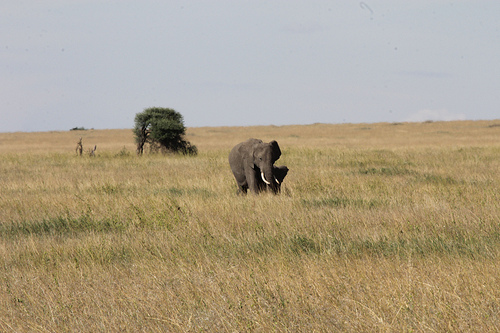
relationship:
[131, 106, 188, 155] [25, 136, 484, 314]
tree in plains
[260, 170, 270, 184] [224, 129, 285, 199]
tusk of elephant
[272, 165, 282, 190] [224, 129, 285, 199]
tusk of elephant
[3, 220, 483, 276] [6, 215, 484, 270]
strip of grass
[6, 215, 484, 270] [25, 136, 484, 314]
grass in plains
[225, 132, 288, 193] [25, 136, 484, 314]
elephant moving across plains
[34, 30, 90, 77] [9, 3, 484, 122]
clouds in sky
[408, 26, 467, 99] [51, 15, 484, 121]
clouds in sky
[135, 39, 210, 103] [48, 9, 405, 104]
clouds in sky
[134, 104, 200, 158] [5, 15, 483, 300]
tree on scene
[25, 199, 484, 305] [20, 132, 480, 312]
grass in field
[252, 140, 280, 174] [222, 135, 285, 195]
head of elephant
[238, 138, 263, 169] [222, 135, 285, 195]
ear of elephant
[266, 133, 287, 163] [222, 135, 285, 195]
ear of elephant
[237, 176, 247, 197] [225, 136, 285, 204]
leg of elephant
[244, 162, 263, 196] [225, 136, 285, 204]
leg of elephant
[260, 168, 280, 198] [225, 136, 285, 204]
leg of elephant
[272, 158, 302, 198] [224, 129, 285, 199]
shadow of elephant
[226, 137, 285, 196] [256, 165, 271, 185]
elephant has tusk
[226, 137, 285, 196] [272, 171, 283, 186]
elephant has tusk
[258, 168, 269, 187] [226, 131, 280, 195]
tusk of elephant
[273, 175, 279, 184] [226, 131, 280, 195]
tusk of elephant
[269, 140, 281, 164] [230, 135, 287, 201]
ear of elephant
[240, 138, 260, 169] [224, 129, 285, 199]
ear of elephant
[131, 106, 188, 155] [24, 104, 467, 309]
tree in a field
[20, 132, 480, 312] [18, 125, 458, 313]
field covered with grass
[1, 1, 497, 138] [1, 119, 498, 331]
sky above land